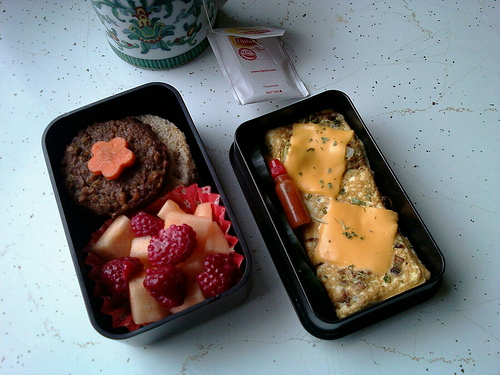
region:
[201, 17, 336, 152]
a packet of teabag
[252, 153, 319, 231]
a red small bottle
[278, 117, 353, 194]
slice of cheese in a black pan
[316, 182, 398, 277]
slice of cheese in a black pan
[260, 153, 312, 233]
red food coloring bottle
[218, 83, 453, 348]
black pan with food in it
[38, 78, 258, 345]
black pan with food in it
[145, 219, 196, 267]
berry in a cupcake holder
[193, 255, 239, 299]
berry in a cupcake holder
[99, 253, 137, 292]
berry in a cupcake holder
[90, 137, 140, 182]
slice of carrot shaped like flower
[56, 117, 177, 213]
hamburger patty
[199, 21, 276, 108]
This is a tea bag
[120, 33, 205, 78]
This is a mug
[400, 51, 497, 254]
This is a white table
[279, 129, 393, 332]
This is a picture of a tv dinner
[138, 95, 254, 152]
This container is black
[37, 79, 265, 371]
the container is black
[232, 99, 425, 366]
the container is black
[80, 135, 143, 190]
an orange star-shaped carrot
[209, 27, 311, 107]
A tea bag.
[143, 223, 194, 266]
A red berry.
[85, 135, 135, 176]
A flower shaped carrot.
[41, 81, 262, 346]
A black box.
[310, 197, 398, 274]
A melted slice of cheese.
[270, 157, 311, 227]
A red plastic bottle.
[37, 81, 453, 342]
Two black lunch boxes.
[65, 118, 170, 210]
A cooked meat pate.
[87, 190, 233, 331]
Sliced mix of fruits.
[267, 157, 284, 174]
A cap on a red plastic bottle.